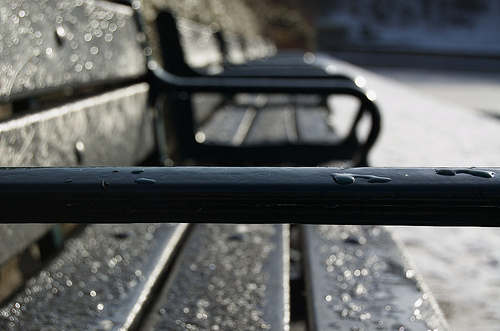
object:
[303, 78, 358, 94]
arm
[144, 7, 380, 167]
bench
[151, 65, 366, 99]
arm rest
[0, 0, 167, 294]
chair back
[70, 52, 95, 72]
nail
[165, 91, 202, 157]
back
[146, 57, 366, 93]
black armrest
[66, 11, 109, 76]
water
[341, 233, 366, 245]
nail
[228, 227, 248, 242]
nail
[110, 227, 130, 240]
nail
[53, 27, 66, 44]
nail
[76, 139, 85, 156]
nail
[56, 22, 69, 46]
screws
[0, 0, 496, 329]
rainy bench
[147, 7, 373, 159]
rainy bench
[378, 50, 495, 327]
sidewalk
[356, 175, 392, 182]
raindrop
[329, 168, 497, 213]
black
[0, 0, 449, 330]
benches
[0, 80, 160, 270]
row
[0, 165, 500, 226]
arm rest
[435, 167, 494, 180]
rain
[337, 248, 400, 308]
rain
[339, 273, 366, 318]
rain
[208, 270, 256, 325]
raindrops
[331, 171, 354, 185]
drops